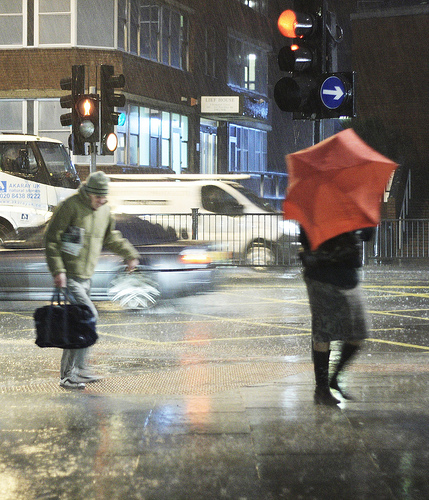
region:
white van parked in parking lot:
[98, 155, 305, 292]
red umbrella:
[264, 108, 404, 248]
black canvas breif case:
[23, 273, 111, 362]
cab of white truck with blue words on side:
[3, 123, 91, 255]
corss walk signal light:
[69, 89, 104, 151]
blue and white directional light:
[316, 75, 361, 116]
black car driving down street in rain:
[0, 196, 229, 311]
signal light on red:
[262, 1, 330, 112]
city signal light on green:
[98, 53, 135, 165]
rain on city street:
[140, 270, 425, 464]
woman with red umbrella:
[270, 110, 399, 429]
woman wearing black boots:
[270, 120, 399, 435]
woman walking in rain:
[276, 109, 386, 447]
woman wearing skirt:
[277, 110, 386, 429]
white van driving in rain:
[110, 149, 294, 269]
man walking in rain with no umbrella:
[40, 147, 131, 402]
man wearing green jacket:
[36, 137, 138, 407]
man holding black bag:
[39, 139, 146, 397]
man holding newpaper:
[37, 148, 147, 396]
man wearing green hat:
[40, 147, 147, 398]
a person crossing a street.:
[28, 166, 139, 393]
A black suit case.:
[30, 295, 104, 359]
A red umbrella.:
[254, 117, 407, 246]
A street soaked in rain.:
[3, 267, 424, 499]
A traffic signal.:
[54, 54, 128, 156]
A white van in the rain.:
[91, 175, 302, 277]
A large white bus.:
[0, 136, 75, 256]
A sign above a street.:
[192, 93, 242, 115]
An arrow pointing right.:
[304, 75, 357, 109]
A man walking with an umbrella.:
[271, 122, 397, 416]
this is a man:
[45, 175, 109, 389]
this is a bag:
[38, 304, 91, 337]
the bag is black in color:
[58, 319, 82, 341]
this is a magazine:
[64, 230, 81, 245]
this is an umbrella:
[314, 142, 362, 214]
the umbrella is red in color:
[318, 192, 370, 201]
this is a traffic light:
[67, 70, 117, 147]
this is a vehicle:
[129, 179, 221, 201]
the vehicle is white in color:
[178, 187, 190, 206]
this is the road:
[187, 284, 256, 330]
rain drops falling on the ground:
[370, 279, 406, 342]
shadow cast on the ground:
[40, 363, 222, 471]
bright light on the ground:
[167, 330, 220, 398]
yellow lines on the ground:
[163, 309, 304, 378]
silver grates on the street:
[99, 368, 193, 409]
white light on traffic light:
[92, 122, 136, 160]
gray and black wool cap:
[74, 156, 133, 204]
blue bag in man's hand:
[22, 274, 116, 362]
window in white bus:
[3, 131, 102, 173]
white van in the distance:
[122, 141, 302, 279]